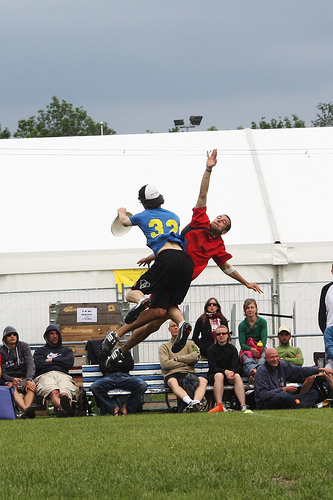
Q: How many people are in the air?
A: Two.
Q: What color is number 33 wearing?
A: Blue.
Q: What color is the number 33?
A: Yellow.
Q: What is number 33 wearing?
A: A hat.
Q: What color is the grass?
A: Green.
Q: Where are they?
A: A field.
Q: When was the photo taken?
A: During the day.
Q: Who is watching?
A: Spectators.